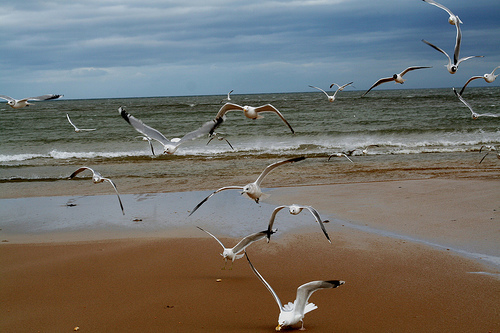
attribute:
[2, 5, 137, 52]
clouds — gray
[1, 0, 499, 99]
sky — blue, cloudy, gray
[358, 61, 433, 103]
bird — white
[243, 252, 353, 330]
bird — white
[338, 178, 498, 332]
sand — wet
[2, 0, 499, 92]
clouds — white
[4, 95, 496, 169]
waters — blue, ocean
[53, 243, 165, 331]
ground — sandy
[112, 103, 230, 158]
bird — white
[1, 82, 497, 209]
ocean — green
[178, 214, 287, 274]
bird — white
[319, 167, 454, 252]
sand — brown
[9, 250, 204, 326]
sand — brown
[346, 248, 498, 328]
sand — brown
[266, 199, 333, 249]
bird — white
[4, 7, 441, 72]
cloud — blue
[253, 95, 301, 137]
wing — big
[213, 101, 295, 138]
bird — flying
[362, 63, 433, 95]
bird — flying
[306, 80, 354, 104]
bird — flying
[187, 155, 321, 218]
bird — flying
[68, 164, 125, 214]
bird — flying